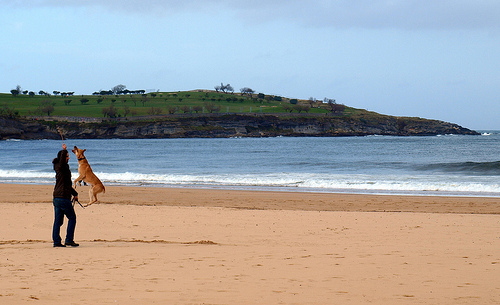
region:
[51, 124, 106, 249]
man playing with a dog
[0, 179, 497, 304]
sand on a beach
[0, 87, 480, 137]
a stone hill covered with grass and trees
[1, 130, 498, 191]
an inlet of water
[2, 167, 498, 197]
waves coming to shore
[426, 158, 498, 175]
a wave before it has broken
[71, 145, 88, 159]
head of a dog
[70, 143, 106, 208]
a dog in the air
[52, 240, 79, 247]
feet of a man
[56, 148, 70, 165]
head of a man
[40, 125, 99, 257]
a person on a beach with a dog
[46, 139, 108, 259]
a dog and a person on a beach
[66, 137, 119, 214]
a dog jumping in the air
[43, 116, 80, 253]
a person with their hand in the air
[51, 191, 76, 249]
a person wearing jeans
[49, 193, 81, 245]
a person wearing blue jeans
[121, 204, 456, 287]
sand on a beach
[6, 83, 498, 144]
a hillside in the distance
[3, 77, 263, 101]
trees on a hillside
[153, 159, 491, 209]
a wave at the beach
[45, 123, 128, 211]
brown dog jumping for a stick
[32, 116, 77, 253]
person wearing all black with black hair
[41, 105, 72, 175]
man throwing a stick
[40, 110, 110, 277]
brown dog jumping for stick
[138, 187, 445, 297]
soft brown sandy beach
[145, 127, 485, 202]
beach of an ocean with crested waves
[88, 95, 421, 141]
cliff leading into water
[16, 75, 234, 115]
animals walking across land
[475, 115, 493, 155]
water splashing against cliff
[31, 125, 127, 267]
man playing with dog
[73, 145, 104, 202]
brown dog in air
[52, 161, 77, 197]
black cotton sweat shirt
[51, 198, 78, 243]
dark blue denim jeans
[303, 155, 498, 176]
wave formed in ocean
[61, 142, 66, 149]
orange ball in hand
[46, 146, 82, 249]
woman standing on beach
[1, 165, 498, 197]
wave breaking on beach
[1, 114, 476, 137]
rock cliff by ocean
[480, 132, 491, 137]
white boat in ocean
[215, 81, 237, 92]
tree with green leaves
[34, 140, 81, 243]
person standing on beach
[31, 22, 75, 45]
white clouds in blue sky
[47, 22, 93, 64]
white clouds in blue sky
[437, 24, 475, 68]
white clouds in blue sky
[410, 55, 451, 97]
white clouds in blue sky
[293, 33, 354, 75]
white clouds in blue sky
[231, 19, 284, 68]
white clouds in blue sky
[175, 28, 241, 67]
white clouds in blue sky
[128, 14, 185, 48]
white clouds in blue sky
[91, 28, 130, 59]
white clouds in blue sky